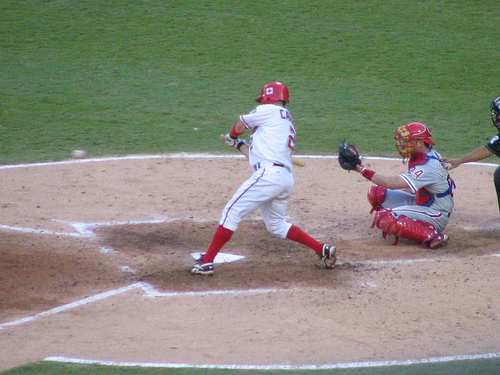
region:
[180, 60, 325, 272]
This man is a batter.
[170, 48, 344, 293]
The man is about to hit a ball.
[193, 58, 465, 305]
These men are baseball players.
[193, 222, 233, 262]
The man's socks are red.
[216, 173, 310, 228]
The man's pants are white.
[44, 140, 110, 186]
This is a baseball.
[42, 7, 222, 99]
This ground is grass.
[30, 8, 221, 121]
The grass here is green.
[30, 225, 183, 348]
The ground here is dirt.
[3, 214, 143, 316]
The dirt here is brown.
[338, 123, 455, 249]
the catcher crouching on the ground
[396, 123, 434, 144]
the helmet on the catcher's head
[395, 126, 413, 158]
the mask on the catcher's head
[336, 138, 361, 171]
the mitt on the catcher's hand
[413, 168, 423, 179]
the 4 on the catcher's jersey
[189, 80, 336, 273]
the batter at the plate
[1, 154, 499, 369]
the white lines on the ground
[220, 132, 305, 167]
the bat in the batter's hands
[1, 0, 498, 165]
the large area of the lush green grass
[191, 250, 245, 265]
the white home base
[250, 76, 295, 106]
A red baseball helmet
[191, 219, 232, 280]
The batter's right leg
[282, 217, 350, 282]
The batter's left leg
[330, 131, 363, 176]
The Umpire's Black Catcher's Mitt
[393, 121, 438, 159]
The Umpire's Red Helmet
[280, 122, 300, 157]
The Number "2" on the man's Jersey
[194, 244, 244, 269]
The Home Run Plate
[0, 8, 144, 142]
A wide plain of grass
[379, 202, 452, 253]
The umpire's bent leg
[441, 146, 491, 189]
The player's extended arm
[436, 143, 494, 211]
umpire's hand on catcher's back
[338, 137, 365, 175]
glove on catcher's hand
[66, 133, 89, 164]
ball batter is trying to hit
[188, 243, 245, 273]
home plate white rubber pad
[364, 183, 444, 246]
catcher's red leg guards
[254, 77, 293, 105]
red helmet on batter's head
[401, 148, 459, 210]
catcher's red and blue safety vest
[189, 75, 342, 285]
batter in white uniform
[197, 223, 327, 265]
batter's long red socks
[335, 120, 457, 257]
catcher in grey uniform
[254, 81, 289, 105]
bright red shiny baseball batting helmet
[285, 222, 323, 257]
long red baseball sock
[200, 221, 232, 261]
left long red baseball sock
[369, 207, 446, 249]
left side catcher's safety pads for the knee and shins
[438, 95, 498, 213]
baseball umpire wearing all black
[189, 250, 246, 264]
home plate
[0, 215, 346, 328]
batter's box where batter's up stands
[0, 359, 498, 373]
line of grass right outside the batter's box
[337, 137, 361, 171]
black leather baseball mitt with a red label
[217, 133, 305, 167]
light shade of wooden baseball bat